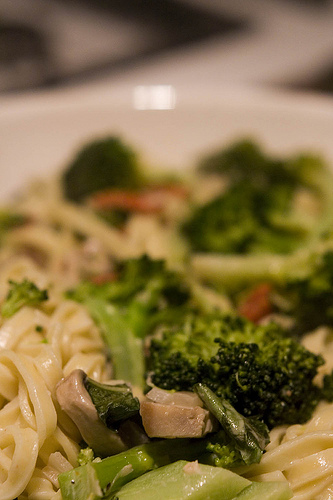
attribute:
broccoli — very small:
[156, 308, 326, 433]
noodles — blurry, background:
[2, 175, 183, 285]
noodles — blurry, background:
[0, 277, 115, 495]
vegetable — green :
[151, 338, 284, 465]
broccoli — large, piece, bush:
[150, 307, 324, 463]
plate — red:
[19, 85, 322, 137]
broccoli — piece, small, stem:
[16, 252, 331, 476]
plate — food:
[1, 82, 332, 496]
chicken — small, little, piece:
[139, 381, 215, 442]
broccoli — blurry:
[196, 181, 273, 249]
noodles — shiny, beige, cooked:
[1, 292, 137, 497]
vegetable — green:
[168, 318, 319, 425]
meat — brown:
[136, 394, 213, 439]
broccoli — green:
[151, 313, 321, 429]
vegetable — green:
[142, 340, 319, 405]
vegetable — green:
[92, 262, 317, 425]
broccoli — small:
[0, 132, 331, 499]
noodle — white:
[5, 352, 58, 447]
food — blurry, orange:
[1, 134, 331, 497]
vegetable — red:
[159, 355, 321, 446]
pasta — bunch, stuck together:
[6, 147, 329, 497]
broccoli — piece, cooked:
[146, 311, 281, 401]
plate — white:
[1, 79, 331, 168]